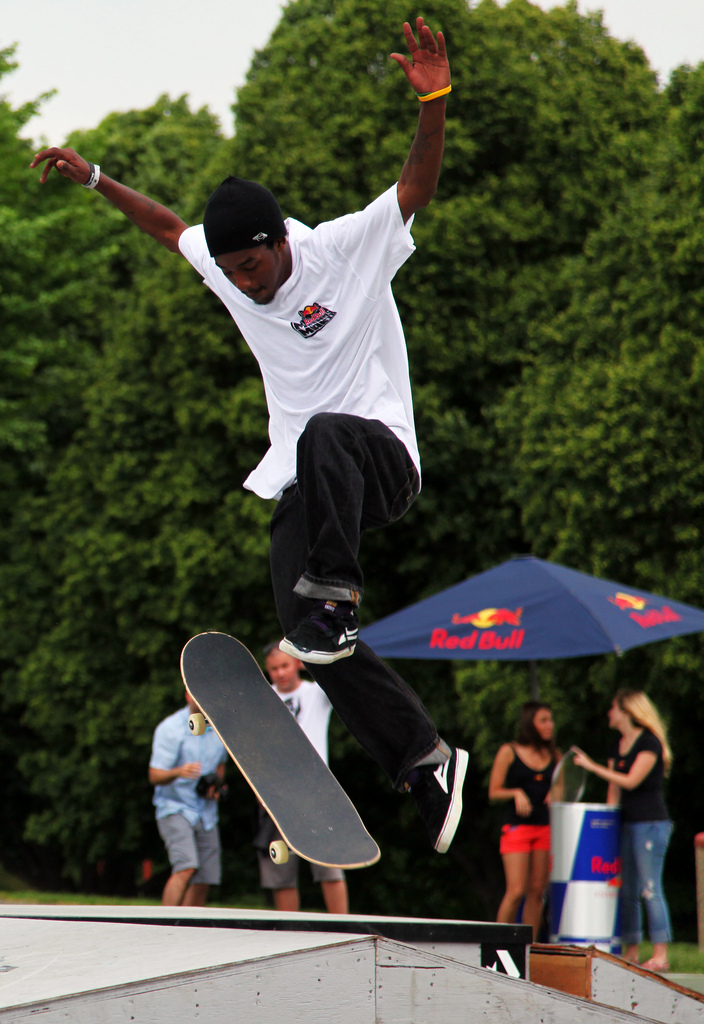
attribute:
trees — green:
[6, 0, 702, 923]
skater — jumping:
[26, 14, 472, 851]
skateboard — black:
[173, 630, 381, 874]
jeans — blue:
[613, 819, 678, 944]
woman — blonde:
[575, 687, 673, 973]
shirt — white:
[177, 177, 439, 498]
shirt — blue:
[149, 706, 225, 829]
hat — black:
[202, 170, 288, 261]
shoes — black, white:
[278, 596, 469, 856]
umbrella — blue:
[343, 553, 702, 669]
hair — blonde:
[618, 687, 677, 781]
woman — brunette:
[487, 694, 563, 942]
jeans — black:
[264, 410, 444, 787]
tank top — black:
[497, 744, 559, 824]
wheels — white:
[186, 709, 293, 873]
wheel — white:
[186, 711, 213, 738]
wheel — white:
[264, 839, 292, 866]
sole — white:
[277, 640, 360, 662]